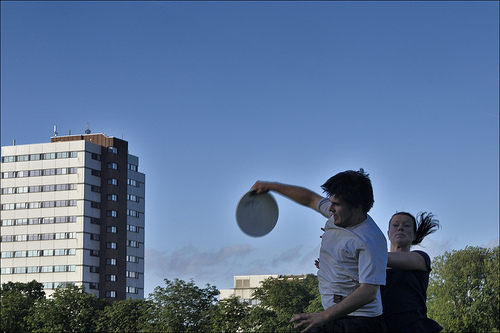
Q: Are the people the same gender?
A: No, they are both male and female.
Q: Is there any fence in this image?
A: No, there are no fences.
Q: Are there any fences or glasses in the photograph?
A: No, there are no fences or glasses.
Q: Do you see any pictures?
A: No, there are no pictures.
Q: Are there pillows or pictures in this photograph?
A: No, there are no pictures or pillows.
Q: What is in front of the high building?
A: The leaf is in front of the building.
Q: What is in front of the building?
A: The leaf is in front of the building.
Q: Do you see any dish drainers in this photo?
A: No, there are no dish drainers.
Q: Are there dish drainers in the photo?
A: No, there are no dish drainers.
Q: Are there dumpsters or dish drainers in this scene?
A: No, there are no dish drainers or dumpsters.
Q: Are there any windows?
A: Yes, there is a window.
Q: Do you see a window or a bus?
A: Yes, there is a window.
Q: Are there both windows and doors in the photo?
A: No, there is a window but no doors.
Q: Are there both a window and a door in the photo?
A: No, there is a window but no doors.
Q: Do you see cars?
A: No, there are no cars.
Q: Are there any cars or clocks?
A: No, there are no cars or clocks.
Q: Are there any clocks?
A: No, there are no clocks.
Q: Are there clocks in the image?
A: No, there are no clocks.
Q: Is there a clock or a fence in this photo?
A: No, there are no clocks or fences.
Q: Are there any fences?
A: No, there are no fences.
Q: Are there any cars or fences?
A: No, there are no fences or cars.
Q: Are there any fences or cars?
A: No, there are no fences or cars.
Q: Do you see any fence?
A: No, there are no fences.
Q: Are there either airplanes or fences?
A: No, there are no fences or airplanes.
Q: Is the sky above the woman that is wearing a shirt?
A: Yes, the sky is above the woman.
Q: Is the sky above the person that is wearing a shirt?
A: Yes, the sky is above the woman.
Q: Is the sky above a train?
A: No, the sky is above the woman.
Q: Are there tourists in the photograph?
A: No, there are no tourists.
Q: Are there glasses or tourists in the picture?
A: No, there are no tourists or glasses.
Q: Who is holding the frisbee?
A: The man is holding the frisbee.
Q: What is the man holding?
A: The man is holding the frisbee.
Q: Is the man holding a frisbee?
A: Yes, the man is holding a frisbee.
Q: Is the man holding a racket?
A: No, the man is holding a frisbee.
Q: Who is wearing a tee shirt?
A: The man is wearing a tee shirt.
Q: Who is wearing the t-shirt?
A: The man is wearing a tee shirt.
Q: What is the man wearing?
A: The man is wearing a tee shirt.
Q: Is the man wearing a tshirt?
A: Yes, the man is wearing a tshirt.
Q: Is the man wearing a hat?
A: No, the man is wearing a tshirt.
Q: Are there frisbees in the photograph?
A: Yes, there is a frisbee.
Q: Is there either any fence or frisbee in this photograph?
A: Yes, there is a frisbee.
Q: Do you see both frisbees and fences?
A: No, there is a frisbee but no fences.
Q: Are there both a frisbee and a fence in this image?
A: No, there is a frisbee but no fences.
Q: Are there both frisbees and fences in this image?
A: No, there is a frisbee but no fences.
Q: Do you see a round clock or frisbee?
A: Yes, there is a round frisbee.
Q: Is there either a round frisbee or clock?
A: Yes, there is a round frisbee.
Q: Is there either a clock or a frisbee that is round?
A: Yes, the frisbee is round.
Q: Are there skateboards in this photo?
A: No, there are no skateboards.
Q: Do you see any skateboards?
A: No, there are no skateboards.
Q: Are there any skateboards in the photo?
A: No, there are no skateboards.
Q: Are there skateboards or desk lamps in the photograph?
A: No, there are no skateboards or desk lamps.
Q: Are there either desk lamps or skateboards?
A: No, there are no skateboards or desk lamps.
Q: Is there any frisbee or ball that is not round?
A: No, there is a frisbee but it is round.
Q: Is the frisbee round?
A: Yes, the frisbee is round.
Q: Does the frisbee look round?
A: Yes, the frisbee is round.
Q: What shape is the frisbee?
A: The frisbee is round.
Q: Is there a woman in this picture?
A: Yes, there is a woman.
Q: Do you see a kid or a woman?
A: Yes, there is a woman.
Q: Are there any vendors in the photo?
A: No, there are no vendors.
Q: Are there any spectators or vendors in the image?
A: No, there are no vendors or spectators.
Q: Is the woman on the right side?
A: Yes, the woman is on the right of the image.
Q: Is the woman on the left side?
A: No, the woman is on the right of the image.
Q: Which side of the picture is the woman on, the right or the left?
A: The woman is on the right of the image.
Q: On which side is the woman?
A: The woman is on the right of the image.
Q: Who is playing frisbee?
A: The woman is playing frisbee.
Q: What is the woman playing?
A: The woman is playing frisbee.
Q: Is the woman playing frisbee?
A: Yes, the woman is playing frisbee.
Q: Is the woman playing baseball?
A: No, the woman is playing frisbee.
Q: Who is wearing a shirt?
A: The woman is wearing a shirt.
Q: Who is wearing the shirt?
A: The woman is wearing a shirt.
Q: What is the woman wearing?
A: The woman is wearing a shirt.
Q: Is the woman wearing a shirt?
A: Yes, the woman is wearing a shirt.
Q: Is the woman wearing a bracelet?
A: No, the woman is wearing a shirt.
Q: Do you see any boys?
A: No, there are no boys.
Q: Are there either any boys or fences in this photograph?
A: No, there are no boys or fences.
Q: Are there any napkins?
A: No, there are no napkins.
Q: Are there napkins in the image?
A: No, there are no napkins.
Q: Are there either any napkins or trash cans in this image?
A: No, there are no napkins or trash cans.